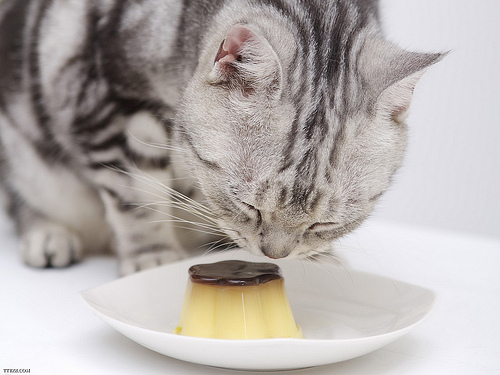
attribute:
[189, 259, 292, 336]
cake — black, brown, white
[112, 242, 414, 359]
plate — white, round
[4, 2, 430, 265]
cat — grey, eating, big, silver, gray, white, old, smelling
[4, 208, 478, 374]
table — white